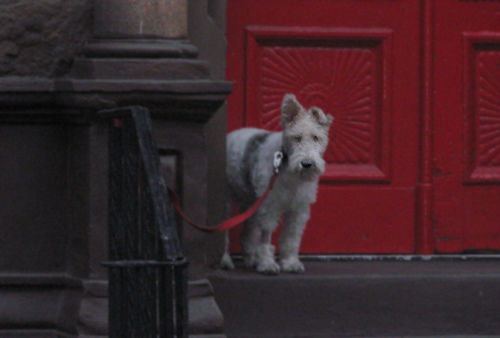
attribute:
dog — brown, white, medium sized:
[220, 94, 333, 276]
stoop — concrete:
[204, 256, 499, 337]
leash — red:
[111, 116, 284, 235]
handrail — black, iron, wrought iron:
[96, 106, 188, 338]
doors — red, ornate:
[227, 1, 499, 256]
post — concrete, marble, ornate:
[54, 1, 233, 338]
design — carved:
[263, 46, 373, 165]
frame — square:
[242, 25, 394, 183]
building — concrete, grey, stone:
[1, 0, 498, 338]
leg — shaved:
[256, 206, 282, 276]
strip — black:
[241, 128, 270, 201]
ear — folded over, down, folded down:
[309, 107, 334, 127]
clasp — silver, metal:
[274, 151, 283, 173]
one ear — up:
[282, 92, 303, 122]